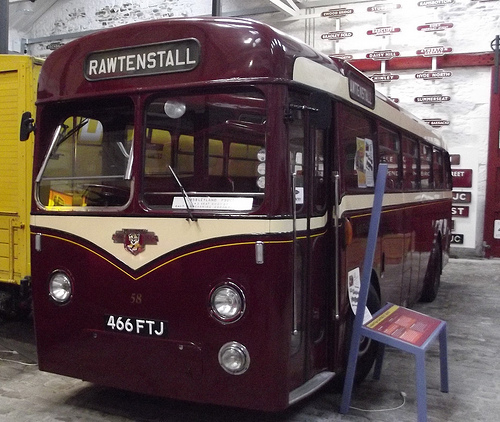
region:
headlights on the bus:
[46, 266, 251, 375]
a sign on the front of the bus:
[76, 35, 202, 82]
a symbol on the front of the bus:
[103, 221, 165, 259]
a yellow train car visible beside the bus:
[2, 52, 274, 287]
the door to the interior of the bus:
[280, 73, 332, 398]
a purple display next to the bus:
[338, 160, 449, 420]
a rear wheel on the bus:
[416, 227, 448, 306]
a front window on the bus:
[33, 87, 136, 218]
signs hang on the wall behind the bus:
[317, 15, 457, 133]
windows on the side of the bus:
[368, 113, 451, 193]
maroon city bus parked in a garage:
[32, 20, 450, 412]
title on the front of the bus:
[86, 50, 202, 75]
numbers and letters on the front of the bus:
[103, 312, 166, 336]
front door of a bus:
[283, 91, 333, 400]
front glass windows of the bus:
[34, 90, 269, 220]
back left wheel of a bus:
[429, 238, 442, 300]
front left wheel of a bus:
[343, 275, 379, 391]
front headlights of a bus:
[42, 264, 251, 322]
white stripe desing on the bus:
[27, 187, 446, 274]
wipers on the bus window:
[166, 157, 206, 227]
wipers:
[157, 163, 200, 206]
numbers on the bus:
[96, 306, 133, 333]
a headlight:
[200, 284, 255, 321]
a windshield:
[46, 118, 123, 195]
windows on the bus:
[378, 138, 455, 178]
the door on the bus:
[295, 107, 340, 369]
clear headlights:
[217, 341, 258, 375]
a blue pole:
[372, 165, 388, 252]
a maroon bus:
[41, 60, 75, 90]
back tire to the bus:
[430, 247, 448, 292]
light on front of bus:
[192, 273, 257, 328]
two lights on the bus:
[26, 250, 271, 320]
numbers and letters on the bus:
[87, 301, 177, 351]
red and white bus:
[71, 225, 216, 321]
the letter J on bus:
[152, 311, 174, 345]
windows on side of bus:
[356, 134, 470, 194]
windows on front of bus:
[30, 65, 275, 221]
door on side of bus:
[247, 90, 385, 356]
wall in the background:
[387, 24, 487, 78]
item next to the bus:
[338, 258, 493, 418]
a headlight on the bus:
[206, 276, 253, 325]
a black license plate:
[98, 302, 173, 342]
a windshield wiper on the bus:
[162, 158, 206, 226]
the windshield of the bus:
[29, 76, 271, 216]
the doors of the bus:
[278, 93, 340, 394]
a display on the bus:
[83, 35, 203, 85]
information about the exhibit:
[357, 300, 447, 358]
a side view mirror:
[14, 105, 39, 144]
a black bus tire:
[415, 233, 450, 303]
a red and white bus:
[11, 10, 455, 420]